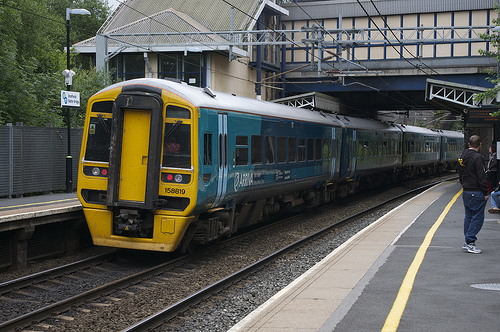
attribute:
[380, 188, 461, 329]
line — yellow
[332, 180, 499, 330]
pavement — black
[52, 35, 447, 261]
train — aqua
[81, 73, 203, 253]
train — yellow 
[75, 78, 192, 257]
yellow front — yellow 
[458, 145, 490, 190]
jacket — black 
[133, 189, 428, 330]
gravel — gray 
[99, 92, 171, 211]
door — closed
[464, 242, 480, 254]
sneaker — white 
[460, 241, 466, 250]
sneaker — white 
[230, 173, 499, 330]
pavement — black 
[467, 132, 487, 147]
hair — dark , short 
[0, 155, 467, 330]
train tracks — large , black 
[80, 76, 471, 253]
train — white , yellow , blue , large 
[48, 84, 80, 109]
sign — small , white 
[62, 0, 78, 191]
pole — tall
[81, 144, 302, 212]
lights — small , red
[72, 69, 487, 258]
train — green , yellow 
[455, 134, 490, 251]
man — one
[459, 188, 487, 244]
pants — blue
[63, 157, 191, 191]
headlights — off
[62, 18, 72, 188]
pole — black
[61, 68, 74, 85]
box — GRAY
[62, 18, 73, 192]
pole — BLACK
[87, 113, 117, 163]
windshield — black 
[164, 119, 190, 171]
windshield — black 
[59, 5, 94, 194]
lamp — black , gray, metal 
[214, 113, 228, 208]
door — light blue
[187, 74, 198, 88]
white sign — small , white 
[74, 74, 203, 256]
front — yellow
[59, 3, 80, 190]
pole — black 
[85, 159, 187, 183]
lights — small 